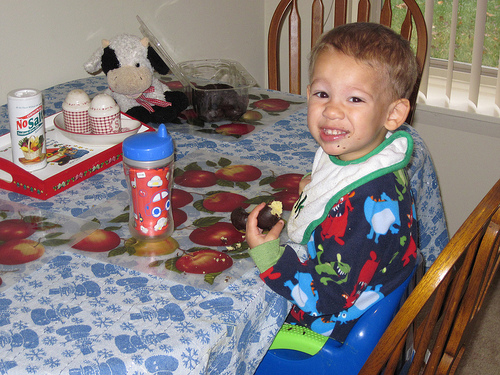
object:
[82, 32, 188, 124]
doll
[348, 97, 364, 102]
eye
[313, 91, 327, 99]
eye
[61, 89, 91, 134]
bottle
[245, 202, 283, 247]
hand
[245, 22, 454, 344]
baby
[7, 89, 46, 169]
food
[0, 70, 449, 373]
table cloth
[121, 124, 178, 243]
feeding bottle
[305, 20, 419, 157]
head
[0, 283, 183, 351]
snowman